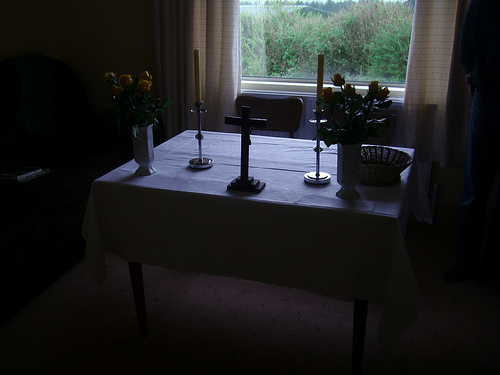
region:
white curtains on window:
[395, 6, 482, 188]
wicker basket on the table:
[356, 142, 412, 197]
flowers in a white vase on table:
[323, 70, 388, 221]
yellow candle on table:
[304, 48, 332, 186]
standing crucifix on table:
[218, 104, 282, 211]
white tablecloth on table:
[69, 188, 398, 280]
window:
[232, 4, 428, 104]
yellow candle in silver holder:
[174, 41, 231, 204]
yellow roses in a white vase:
[96, 61, 174, 183]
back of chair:
[265, 83, 307, 137]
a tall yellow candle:
[310, 52, 324, 105]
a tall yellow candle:
[191, 47, 205, 93]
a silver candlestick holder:
[185, 100, 213, 171]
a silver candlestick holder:
[303, 107, 330, 186]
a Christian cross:
[220, 105, 270, 192]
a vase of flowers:
[87, 65, 165, 181]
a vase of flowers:
[312, 73, 389, 197]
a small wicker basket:
[351, 144, 416, 190]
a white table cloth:
[81, 116, 429, 301]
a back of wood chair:
[227, 87, 305, 134]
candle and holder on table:
[185, 48, 221, 159]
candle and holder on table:
[301, 63, 331, 191]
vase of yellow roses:
[116, 67, 167, 174]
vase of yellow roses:
[329, 70, 374, 204]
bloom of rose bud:
[138, 79, 158, 98]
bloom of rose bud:
[123, 74, 142, 85]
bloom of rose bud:
[375, 85, 394, 99]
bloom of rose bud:
[327, 67, 347, 84]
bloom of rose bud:
[323, 87, 337, 99]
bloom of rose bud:
[339, 80, 356, 97]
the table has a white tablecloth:
[73, 42, 440, 329]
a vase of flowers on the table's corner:
[98, 57, 165, 179]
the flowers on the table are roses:
[101, 62, 161, 124]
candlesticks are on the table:
[181, 45, 330, 187]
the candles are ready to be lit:
[187, 40, 328, 117]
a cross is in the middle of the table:
[219, 100, 270, 196]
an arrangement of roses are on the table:
[309, 70, 400, 220]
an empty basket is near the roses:
[355, 137, 412, 190]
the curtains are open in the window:
[160, 5, 465, 172]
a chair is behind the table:
[227, 91, 306, 146]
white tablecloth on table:
[112, 100, 414, 330]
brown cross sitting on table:
[206, 101, 298, 212]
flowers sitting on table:
[92, 36, 184, 194]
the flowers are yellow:
[91, 53, 173, 118]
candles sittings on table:
[175, 46, 232, 186]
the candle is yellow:
[174, 41, 232, 122]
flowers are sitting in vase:
[79, 60, 207, 257]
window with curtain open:
[121, 0, 488, 241]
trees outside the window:
[244, 0, 406, 100]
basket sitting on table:
[343, 133, 415, 198]